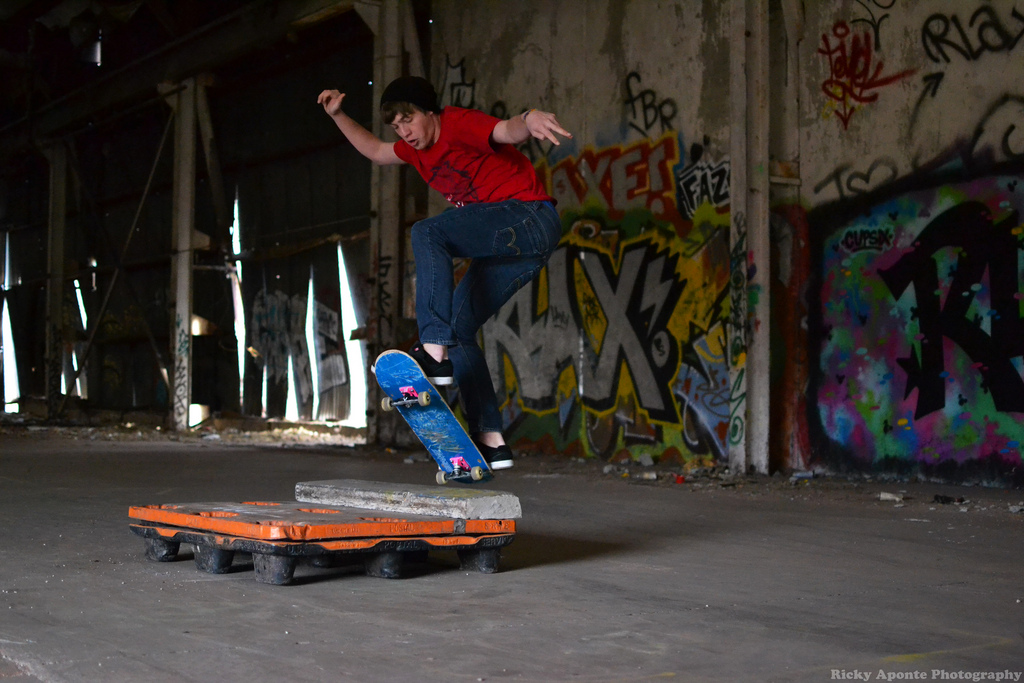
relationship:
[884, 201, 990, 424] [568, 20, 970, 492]
black graffiti on wall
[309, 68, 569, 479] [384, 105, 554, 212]
boy wearing red shirt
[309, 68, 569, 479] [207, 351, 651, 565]
boy on skateboard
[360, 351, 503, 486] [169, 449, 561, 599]
skateboard on ground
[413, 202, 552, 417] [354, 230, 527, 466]
jeans on boy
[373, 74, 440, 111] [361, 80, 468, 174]
black hat on person's head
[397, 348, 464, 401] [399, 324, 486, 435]
shoe on foot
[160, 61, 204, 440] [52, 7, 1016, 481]
pole leaning on wall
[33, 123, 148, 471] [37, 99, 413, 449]
pole by door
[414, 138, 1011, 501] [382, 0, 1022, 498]
graffiti on wall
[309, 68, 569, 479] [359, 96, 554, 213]
boy wearing red shirt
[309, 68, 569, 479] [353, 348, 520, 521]
boy on skateboard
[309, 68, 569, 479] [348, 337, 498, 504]
boy on skateboard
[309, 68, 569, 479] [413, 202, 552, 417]
boy wearing jeans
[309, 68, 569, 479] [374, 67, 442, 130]
boy wearing black hat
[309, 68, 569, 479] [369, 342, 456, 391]
boy wearing shoe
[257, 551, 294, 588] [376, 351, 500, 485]
wheels are on skateboard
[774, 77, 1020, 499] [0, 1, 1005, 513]
graffiti on wall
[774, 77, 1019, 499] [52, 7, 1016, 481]
graffiti on wall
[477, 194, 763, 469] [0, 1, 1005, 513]
graphiti on wall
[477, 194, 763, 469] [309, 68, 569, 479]
graphiti behind boy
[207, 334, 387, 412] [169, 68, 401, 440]
graphiti on door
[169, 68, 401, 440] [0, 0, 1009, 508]
door on building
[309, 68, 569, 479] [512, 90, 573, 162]
boy has hand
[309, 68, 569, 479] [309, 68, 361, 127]
boy has hand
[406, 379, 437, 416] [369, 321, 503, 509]
wheel on skateboard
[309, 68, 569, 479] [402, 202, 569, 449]
boy wearing jeans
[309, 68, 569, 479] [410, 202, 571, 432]
boy wearing jeans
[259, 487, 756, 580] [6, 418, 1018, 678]
shadow across ground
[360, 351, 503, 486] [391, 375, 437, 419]
skateboard has wheel